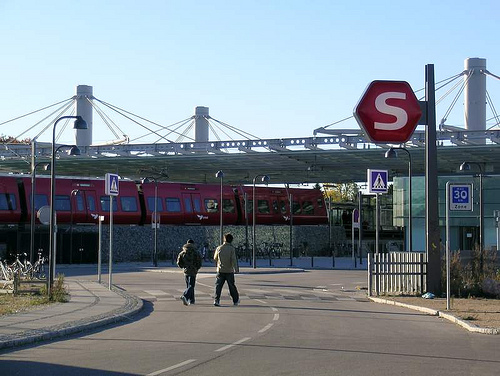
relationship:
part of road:
[274, 344, 340, 358] [151, 305, 373, 374]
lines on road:
[174, 341, 232, 372] [151, 305, 373, 374]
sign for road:
[356, 81, 415, 149] [151, 305, 373, 374]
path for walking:
[46, 301, 95, 322] [26, 281, 118, 322]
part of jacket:
[228, 257, 241, 265] [211, 241, 238, 275]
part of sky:
[218, 21, 281, 44] [6, 1, 445, 60]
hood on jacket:
[221, 241, 233, 247] [211, 241, 238, 275]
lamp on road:
[43, 115, 90, 305] [3, 259, 499, 374]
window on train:
[165, 194, 187, 213] [7, 175, 327, 214]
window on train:
[257, 195, 270, 214] [7, 175, 327, 214]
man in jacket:
[205, 220, 247, 308] [211, 241, 238, 275]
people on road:
[164, 225, 246, 308] [3, 259, 499, 374]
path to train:
[46, 301, 95, 322] [7, 175, 327, 214]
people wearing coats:
[164, 225, 246, 308] [171, 241, 247, 273]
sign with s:
[356, 81, 415, 149] [374, 92, 405, 136]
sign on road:
[356, 81, 415, 149] [3, 259, 499, 374]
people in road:
[164, 225, 246, 308] [151, 305, 373, 374]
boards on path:
[45, 324, 63, 335] [46, 301, 95, 322]